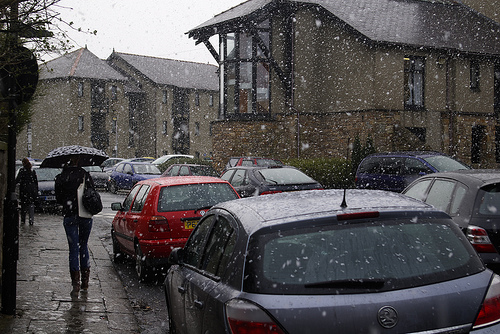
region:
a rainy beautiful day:
[6, 9, 496, 329]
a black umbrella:
[38, 144, 104, 166]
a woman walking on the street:
[41, 144, 107, 295]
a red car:
[115, 177, 235, 263]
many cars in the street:
[116, 137, 498, 331]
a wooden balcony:
[201, 2, 293, 119]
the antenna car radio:
[338, 133, 350, 208]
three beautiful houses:
[25, 0, 490, 161]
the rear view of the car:
[235, 220, 492, 332]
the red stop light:
[336, 210, 380, 220]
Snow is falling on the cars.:
[1, 145, 499, 330]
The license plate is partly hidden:
[183, 217, 209, 229]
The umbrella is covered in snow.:
[38, 141, 111, 168]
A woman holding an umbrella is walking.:
[39, 142, 109, 297]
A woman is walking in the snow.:
[13, 157, 42, 229]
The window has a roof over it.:
[179, 0, 291, 120]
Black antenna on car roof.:
[335, 137, 355, 209]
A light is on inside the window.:
[401, 56, 426, 110]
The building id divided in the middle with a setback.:
[31, 46, 215, 153]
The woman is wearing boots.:
[56, 154, 91, 298]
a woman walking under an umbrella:
[37, 142, 111, 293]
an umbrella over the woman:
[36, 141, 108, 170]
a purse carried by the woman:
[80, 175, 102, 215]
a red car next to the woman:
[110, 173, 242, 265]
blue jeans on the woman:
[63, 210, 95, 267]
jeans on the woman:
[69, 262, 91, 294]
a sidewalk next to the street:
[0, 198, 137, 332]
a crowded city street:
[87, 160, 279, 330]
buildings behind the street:
[9, 0, 497, 180]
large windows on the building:
[219, 16, 275, 113]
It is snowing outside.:
[0, 1, 495, 326]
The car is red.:
[105, 176, 240, 271]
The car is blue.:
[157, 186, 489, 331]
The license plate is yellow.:
[172, 215, 197, 235]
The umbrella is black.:
[38, 140, 109, 165]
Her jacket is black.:
[42, 166, 92, 214]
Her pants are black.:
[55, 210, 95, 290]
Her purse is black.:
[72, 166, 102, 207]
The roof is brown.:
[45, 45, 217, 86]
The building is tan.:
[17, 70, 217, 165]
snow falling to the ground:
[301, 9, 371, 156]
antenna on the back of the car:
[340, 130, 355, 210]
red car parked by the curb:
[109, 169, 230, 288]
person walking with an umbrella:
[33, 135, 108, 297]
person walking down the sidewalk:
[9, 154, 44, 234]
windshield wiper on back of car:
[256, 168, 279, 185]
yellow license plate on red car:
[179, 214, 199, 234]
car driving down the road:
[396, 157, 496, 240]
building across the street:
[188, 5, 485, 168]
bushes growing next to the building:
[297, 151, 358, 186]